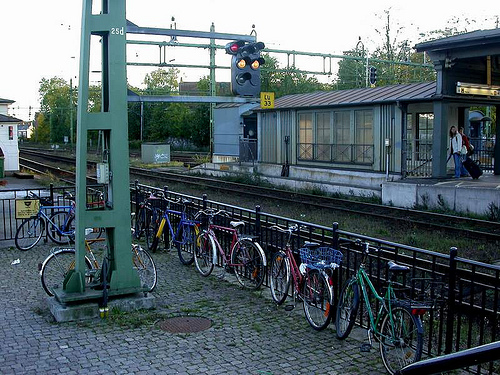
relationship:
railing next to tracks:
[139, 180, 494, 340] [195, 172, 497, 291]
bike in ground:
[13, 187, 93, 248] [448, 150, 457, 166]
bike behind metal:
[13, 187, 93, 248] [57, 0, 149, 309]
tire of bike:
[128, 240, 158, 297] [38, 237, 158, 300]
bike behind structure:
[38, 237, 158, 300] [47, 0, 161, 321]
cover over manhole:
[156, 312, 210, 332] [154, 297, 219, 345]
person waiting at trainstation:
[449, 125, 472, 178] [9, 35, 480, 362]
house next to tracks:
[214, 53, 498, 351] [19, 140, 479, 351]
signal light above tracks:
[224, 35, 269, 99] [19, 140, 500, 368]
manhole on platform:
[141, 307, 226, 345] [10, 235, 315, 359]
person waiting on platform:
[449, 125, 472, 178] [373, 147, 483, 209]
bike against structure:
[25, 215, 179, 305] [57, 3, 443, 301]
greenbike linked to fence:
[335, 237, 424, 374] [0, 179, 500, 374]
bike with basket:
[260, 216, 339, 327] [296, 235, 346, 273]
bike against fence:
[260, 216, 339, 327] [6, 172, 485, 355]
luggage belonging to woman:
[462, 153, 483, 183] [441, 123, 468, 178]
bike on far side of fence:
[14, 197, 102, 252] [0, 179, 500, 374]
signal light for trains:
[224, 41, 265, 95] [228, 30, 286, 122]